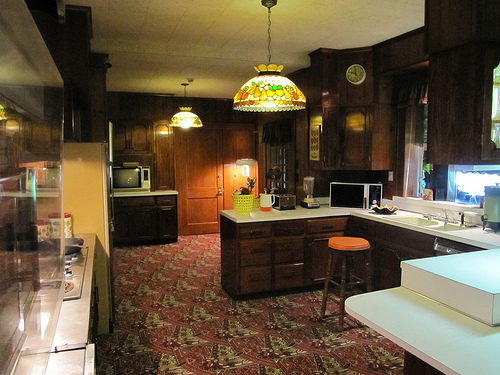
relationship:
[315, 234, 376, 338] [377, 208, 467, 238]
stool in front of sink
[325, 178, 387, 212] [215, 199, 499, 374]
microwave on counter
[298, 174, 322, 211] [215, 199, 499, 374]
blender on counter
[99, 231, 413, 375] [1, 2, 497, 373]
carpet in kitchen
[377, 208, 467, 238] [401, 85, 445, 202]
sink in front of window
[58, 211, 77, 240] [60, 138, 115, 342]
cannister next to refrigerator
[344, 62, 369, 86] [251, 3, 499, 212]
clock on wall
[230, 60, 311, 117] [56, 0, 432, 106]
ceiling light hanging from ceiling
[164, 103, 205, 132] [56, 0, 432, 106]
ceiling light hanging from ceiling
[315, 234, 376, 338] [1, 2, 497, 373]
stool in kitchen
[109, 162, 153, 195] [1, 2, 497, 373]
tv in kitchen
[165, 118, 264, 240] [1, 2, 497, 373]
door of kitchen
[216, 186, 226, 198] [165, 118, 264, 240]
handle on door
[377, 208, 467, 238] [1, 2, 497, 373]
sink in kitchen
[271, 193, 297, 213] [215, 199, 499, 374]
toaster on counter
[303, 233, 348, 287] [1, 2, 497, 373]
cabinet in kitchen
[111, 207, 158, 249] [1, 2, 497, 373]
cabinet in kitchen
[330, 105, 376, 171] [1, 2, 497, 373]
cabinet in kitchen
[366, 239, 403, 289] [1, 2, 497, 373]
cabinet in kitchen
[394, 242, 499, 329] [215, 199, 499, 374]
box on counter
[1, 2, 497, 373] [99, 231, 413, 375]
kitchen has carpet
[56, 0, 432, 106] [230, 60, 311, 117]
ceiling has ceiling light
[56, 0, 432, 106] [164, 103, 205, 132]
ceiling has ceiling light